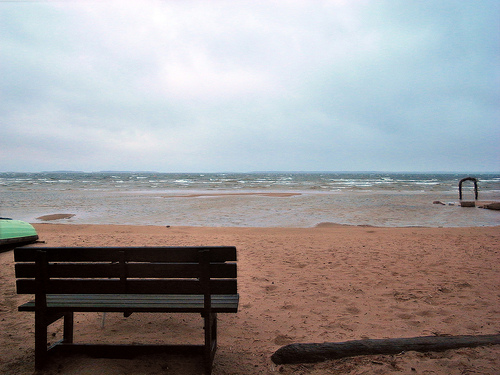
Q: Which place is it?
A: It is a beach.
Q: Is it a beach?
A: Yes, it is a beach.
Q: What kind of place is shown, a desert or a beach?
A: It is a beach.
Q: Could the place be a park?
A: No, it is a beach.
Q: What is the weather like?
A: It is cloudy.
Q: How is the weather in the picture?
A: It is cloudy.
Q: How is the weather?
A: It is cloudy.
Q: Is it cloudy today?
A: Yes, it is cloudy.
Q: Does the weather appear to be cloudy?
A: Yes, it is cloudy.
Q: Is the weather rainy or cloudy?
A: It is cloudy.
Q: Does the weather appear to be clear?
A: No, it is cloudy.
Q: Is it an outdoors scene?
A: Yes, it is outdoors.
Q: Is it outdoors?
A: Yes, it is outdoors.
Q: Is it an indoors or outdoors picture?
A: It is outdoors.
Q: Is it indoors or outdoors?
A: It is outdoors.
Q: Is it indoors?
A: No, it is outdoors.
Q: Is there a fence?
A: No, there are no fences.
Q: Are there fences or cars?
A: No, there are no fences or cars.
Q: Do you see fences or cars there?
A: No, there are no fences or cars.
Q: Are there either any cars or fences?
A: No, there are no fences or cars.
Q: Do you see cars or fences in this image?
A: No, there are no fences or cars.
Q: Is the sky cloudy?
A: Yes, the sky is cloudy.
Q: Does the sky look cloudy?
A: Yes, the sky is cloudy.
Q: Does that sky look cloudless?
A: No, the sky is cloudy.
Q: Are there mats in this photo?
A: No, there are no mats.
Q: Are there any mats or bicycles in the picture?
A: No, there are no mats or bicycles.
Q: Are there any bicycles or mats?
A: No, there are no mats or bicycles.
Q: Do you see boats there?
A: Yes, there is a boat.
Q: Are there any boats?
A: Yes, there is a boat.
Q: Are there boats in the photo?
A: Yes, there is a boat.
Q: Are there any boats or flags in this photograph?
A: Yes, there is a boat.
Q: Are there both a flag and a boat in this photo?
A: No, there is a boat but no flags.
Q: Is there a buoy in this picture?
A: No, there are no buoys.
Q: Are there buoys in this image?
A: No, there are no buoys.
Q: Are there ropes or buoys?
A: No, there are no buoys or ropes.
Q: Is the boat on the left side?
A: Yes, the boat is on the left of the image.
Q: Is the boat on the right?
A: No, the boat is on the left of the image.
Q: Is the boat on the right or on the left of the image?
A: The boat is on the left of the image.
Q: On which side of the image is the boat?
A: The boat is on the left of the image.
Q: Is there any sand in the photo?
A: Yes, there is sand.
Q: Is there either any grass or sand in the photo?
A: Yes, there is sand.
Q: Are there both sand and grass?
A: No, there is sand but no grass.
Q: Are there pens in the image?
A: No, there are no pens.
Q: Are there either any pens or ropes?
A: No, there are no pens or ropes.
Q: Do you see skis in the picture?
A: No, there are no skis.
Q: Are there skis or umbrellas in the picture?
A: No, there are no skis or umbrellas.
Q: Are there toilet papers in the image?
A: No, there are no toilet papers.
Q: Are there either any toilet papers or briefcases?
A: No, there are no toilet papers or briefcases.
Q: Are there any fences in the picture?
A: No, there are no fences.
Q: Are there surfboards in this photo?
A: No, there are no surfboards.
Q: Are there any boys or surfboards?
A: No, there are no surfboards or boys.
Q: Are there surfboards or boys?
A: No, there are no surfboards or boys.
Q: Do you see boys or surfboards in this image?
A: No, there are no surfboards or boys.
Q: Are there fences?
A: No, there are no fences.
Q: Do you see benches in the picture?
A: Yes, there is a bench.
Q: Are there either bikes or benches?
A: Yes, there is a bench.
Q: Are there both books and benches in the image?
A: No, there is a bench but no books.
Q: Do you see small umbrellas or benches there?
A: Yes, there is a small bench.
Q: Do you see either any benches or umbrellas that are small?
A: Yes, the bench is small.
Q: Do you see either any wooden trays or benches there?
A: Yes, there is a wood bench.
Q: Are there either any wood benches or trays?
A: Yes, there is a wood bench.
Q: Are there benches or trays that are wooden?
A: Yes, the bench is wooden.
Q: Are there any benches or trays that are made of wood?
A: Yes, the bench is made of wood.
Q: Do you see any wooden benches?
A: Yes, there is a wood bench.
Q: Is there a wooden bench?
A: Yes, there is a wood bench.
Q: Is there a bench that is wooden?
A: Yes, there is a bench that is wooden.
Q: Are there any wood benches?
A: Yes, there is a bench that is made of wood.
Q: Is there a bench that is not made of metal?
A: Yes, there is a bench that is made of wood.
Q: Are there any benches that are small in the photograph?
A: Yes, there is a small bench.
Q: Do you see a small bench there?
A: Yes, there is a small bench.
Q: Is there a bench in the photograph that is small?
A: Yes, there is a bench that is small.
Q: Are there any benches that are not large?
A: Yes, there is a small bench.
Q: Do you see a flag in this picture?
A: No, there are no flags.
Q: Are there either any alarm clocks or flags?
A: No, there are no flags or alarm clocks.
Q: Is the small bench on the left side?
A: Yes, the bench is on the left of the image.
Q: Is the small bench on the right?
A: No, the bench is on the left of the image.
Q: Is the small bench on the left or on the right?
A: The bench is on the left of the image.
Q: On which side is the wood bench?
A: The bench is on the left of the image.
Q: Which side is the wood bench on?
A: The bench is on the left of the image.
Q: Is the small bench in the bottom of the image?
A: Yes, the bench is in the bottom of the image.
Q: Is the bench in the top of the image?
A: No, the bench is in the bottom of the image.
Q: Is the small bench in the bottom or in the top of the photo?
A: The bench is in the bottom of the image.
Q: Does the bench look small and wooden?
A: Yes, the bench is small and wooden.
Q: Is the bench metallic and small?
A: No, the bench is small but wooden.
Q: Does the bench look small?
A: Yes, the bench is small.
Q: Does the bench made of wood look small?
A: Yes, the bench is small.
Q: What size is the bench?
A: The bench is small.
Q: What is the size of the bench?
A: The bench is small.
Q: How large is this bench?
A: The bench is small.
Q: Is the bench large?
A: No, the bench is small.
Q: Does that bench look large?
A: No, the bench is small.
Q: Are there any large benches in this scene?
A: No, there is a bench but it is small.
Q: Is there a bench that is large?
A: No, there is a bench but it is small.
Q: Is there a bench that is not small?
A: No, there is a bench but it is small.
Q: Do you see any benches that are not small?
A: No, there is a bench but it is small.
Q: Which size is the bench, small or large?
A: The bench is small.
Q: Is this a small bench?
A: Yes, this is a small bench.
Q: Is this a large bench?
A: No, this is a small bench.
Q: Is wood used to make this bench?
A: Yes, the bench is made of wood.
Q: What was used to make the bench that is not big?
A: The bench is made of wood.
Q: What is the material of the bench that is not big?
A: The bench is made of wood.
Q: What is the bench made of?
A: The bench is made of wood.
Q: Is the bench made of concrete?
A: No, the bench is made of wood.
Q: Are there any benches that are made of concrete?
A: No, there is a bench but it is made of wood.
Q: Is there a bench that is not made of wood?
A: No, there is a bench but it is made of wood.